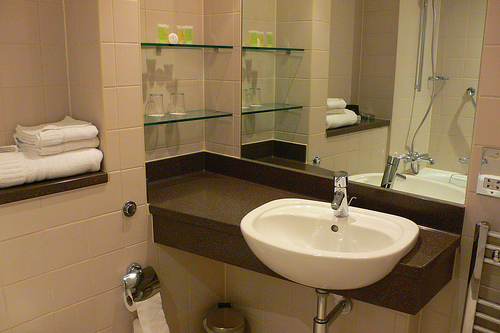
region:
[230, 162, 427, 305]
a white sink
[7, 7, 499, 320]
a scene in the bathroom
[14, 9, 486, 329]
a scene inside a bathroom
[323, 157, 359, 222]
a silver faucet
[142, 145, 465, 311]
a brown counter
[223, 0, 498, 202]
a bathroom mirror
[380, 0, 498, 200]
a bathtub seen in the mirror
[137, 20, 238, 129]
a couple of shelf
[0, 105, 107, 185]
a couple of white towels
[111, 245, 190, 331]
a white toilet paper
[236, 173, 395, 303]
white sink in bathroom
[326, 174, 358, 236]
silver faucet in sink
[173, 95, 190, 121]
clear glass on shelf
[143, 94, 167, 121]
clear glass on shelf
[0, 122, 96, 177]
towels on a shelf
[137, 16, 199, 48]
toiletries on top shelf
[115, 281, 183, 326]
toilet paper on silver roll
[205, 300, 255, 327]
garbage can in corner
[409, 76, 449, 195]
reflection of bath tub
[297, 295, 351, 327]
silver pipes under sink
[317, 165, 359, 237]
silver fixtures on a sink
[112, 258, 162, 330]
a silver toilet paper holder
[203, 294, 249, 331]
a silver and black trash can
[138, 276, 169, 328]
a white roll of toilet paper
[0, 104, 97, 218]
folded white towels on shelf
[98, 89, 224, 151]
a glass shelf with wo glasses on it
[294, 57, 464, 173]
reflection in a mirror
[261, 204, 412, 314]
white sink basi and drain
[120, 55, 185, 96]
shadow on the tile wall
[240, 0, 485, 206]
Mirror on the wall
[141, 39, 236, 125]
Glass shelves on the wall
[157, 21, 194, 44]
Toilette on the top glass shelf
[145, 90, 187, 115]
Glasses on the bottom shelf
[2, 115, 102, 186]
Towels on the counter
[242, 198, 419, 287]
White sink on the counter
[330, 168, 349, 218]
Faucet over the sink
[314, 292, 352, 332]
Pipes under the sink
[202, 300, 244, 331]
Garbage can under the sink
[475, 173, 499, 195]
Plug in on the wall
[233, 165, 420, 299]
Bathroom sink with faucet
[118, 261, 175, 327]
Metal toilet paper holder with toilet paper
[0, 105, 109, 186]
A stack of folded towels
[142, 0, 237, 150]
Two glass shelves with bath products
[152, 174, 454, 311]
Wood counter top with sink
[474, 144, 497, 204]
Electrical outlet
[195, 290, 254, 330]
Small metal trash can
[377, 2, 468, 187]
Reflection of a shower in the mirror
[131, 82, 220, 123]
Two drinking glasses on a glass shelf